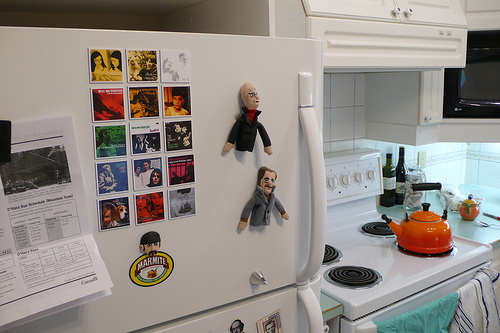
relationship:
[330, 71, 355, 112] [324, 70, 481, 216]
tile in a wall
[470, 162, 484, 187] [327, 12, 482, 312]
tile in a wall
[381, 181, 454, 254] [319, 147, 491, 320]
kettle on stove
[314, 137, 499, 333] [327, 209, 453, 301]
stove with burners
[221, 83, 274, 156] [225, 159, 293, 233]
fridge magnet of man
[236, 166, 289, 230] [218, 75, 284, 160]
fridge magnet of man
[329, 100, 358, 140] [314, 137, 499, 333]
tile above stove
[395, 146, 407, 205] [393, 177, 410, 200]
bottle with a label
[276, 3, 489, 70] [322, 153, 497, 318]
cabinet above stove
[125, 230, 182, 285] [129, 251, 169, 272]
magnet advertising marmite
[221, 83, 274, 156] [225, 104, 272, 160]
fridge magnet in suit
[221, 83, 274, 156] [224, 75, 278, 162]
fridge magnet as magnet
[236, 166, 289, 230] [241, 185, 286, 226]
fridge magnet in coat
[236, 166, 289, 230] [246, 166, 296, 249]
fridge magnet as magnet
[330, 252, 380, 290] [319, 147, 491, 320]
burner on stove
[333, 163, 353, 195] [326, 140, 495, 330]
knob for stove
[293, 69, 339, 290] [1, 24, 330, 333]
handle for freezer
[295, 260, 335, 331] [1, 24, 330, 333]
handle for freezer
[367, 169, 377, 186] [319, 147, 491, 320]
knob for stove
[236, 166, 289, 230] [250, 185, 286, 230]
fridge magnet in coat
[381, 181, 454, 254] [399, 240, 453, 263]
kettle sitting on burner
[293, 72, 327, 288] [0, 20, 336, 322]
handle on door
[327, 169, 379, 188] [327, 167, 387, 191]
nobs of nobs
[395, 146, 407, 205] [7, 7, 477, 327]
bottle in kitchen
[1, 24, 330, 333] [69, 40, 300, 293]
freezer with magnets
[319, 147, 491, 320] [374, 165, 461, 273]
stove with teapot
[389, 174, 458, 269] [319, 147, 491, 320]
kettle on stove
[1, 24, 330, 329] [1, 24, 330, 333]
freezer built into freezer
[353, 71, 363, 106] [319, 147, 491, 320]
tile mounted above stove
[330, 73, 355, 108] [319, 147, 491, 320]
tile mounted above stove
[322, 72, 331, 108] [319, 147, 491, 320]
tile mounted above stove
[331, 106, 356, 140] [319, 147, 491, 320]
tile mounted above stove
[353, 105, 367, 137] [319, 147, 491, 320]
tile mounted above stove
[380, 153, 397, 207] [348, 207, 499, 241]
bottle standing on top of counter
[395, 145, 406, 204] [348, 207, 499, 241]
bottle standing on top of counter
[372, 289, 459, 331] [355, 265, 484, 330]
kitchen towel hanging from oven handle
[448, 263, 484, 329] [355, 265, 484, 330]
kitchen towel hanging from oven handle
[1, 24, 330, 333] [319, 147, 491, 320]
freezer standing next to stove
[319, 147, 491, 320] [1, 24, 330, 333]
stove standing next to freezer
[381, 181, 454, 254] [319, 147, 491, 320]
kettle standing on top of stove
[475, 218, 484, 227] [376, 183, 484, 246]
spoon lying on top of counter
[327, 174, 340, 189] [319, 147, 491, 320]
knob controlling stove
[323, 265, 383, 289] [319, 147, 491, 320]
burner built into stove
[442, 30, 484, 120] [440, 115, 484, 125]
microwave sitting on shelf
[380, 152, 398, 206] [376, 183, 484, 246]
bottle standing on top of counter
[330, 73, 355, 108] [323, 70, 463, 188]
tile covering wall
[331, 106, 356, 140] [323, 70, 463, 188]
tile covering wall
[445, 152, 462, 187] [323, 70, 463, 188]
tile covering wall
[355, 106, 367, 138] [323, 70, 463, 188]
tile covering wall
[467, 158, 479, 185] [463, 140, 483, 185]
tile covering wall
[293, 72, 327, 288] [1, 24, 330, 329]
handle mounted on freezer